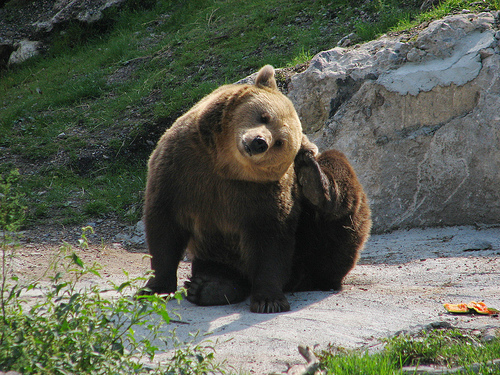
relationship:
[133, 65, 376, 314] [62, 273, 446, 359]
bear on ground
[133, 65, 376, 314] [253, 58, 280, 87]
bear scratching ear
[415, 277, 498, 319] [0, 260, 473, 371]
object on ground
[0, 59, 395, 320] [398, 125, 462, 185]
bear on ground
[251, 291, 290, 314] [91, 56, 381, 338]
bear paw of bear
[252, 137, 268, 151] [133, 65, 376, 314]
nose of bear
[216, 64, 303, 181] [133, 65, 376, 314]
head of bear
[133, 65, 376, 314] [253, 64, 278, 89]
bear scratching ear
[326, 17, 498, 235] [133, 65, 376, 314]
rock behind bear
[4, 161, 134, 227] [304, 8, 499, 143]
weeds growing beside rock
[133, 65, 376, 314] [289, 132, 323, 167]
bear scratching ear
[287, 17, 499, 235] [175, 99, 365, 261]
rock behind bear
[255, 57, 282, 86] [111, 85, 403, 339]
ear of bear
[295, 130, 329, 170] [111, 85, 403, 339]
ear of bear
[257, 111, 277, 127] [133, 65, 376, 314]
eye of bear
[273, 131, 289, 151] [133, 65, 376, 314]
eye of bear